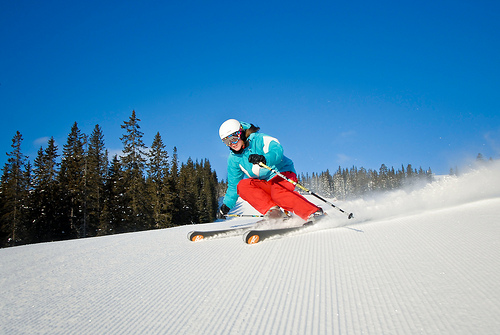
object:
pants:
[235, 171, 321, 222]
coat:
[217, 132, 297, 211]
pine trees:
[320, 169, 332, 197]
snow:
[317, 157, 500, 233]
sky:
[1, 0, 500, 185]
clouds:
[93, 138, 172, 168]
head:
[217, 118, 249, 154]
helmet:
[218, 118, 243, 140]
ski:
[186, 211, 273, 244]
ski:
[243, 218, 319, 246]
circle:
[190, 235, 204, 242]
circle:
[248, 234, 259, 244]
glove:
[247, 153, 268, 167]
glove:
[215, 203, 231, 219]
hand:
[248, 154, 267, 168]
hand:
[215, 203, 231, 220]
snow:
[0, 159, 499, 334]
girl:
[215, 117, 324, 226]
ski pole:
[256, 160, 357, 222]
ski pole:
[219, 211, 266, 221]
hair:
[245, 122, 261, 138]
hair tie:
[238, 121, 252, 130]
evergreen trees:
[0, 130, 32, 251]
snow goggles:
[222, 124, 243, 146]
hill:
[1, 158, 499, 335]